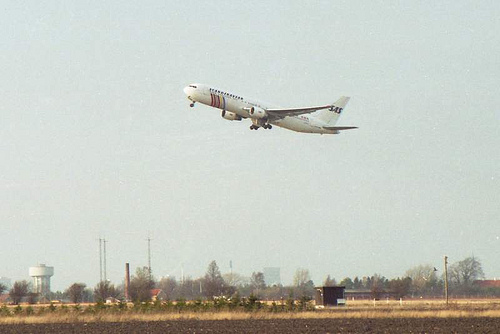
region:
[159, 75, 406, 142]
a plane taking off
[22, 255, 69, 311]
water tower in the distance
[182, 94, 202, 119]
front landing gear on the plane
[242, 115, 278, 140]
rear landing gear of the plane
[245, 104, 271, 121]
jet engine of the plane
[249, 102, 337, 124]
left wing of the plane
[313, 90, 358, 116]
tail fin of the plane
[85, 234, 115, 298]
posts in the distance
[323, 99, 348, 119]
logo of the airline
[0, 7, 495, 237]
a light blue sky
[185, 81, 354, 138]
airplane flying in sky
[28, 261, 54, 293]
white water tower by tree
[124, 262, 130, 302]
brown brick smoke stack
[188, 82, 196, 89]
cockpit window on airplane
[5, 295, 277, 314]
green bushes by field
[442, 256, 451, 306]
brown wooden light pole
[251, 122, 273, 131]
black rubber plane tires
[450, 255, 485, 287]
tree with no leaves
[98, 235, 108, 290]
two wooden electrical towers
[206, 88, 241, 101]
windows on side of plane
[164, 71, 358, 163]
commercial airplane in sky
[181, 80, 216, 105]
nose of commercial airplane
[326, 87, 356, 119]
tail of commercial airplane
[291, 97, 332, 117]
wing of commercial airplane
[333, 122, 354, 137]
wing of commercial airplane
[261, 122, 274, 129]
wheel of commercial airplane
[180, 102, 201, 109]
wheel of commercial airplane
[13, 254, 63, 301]
water tower on ground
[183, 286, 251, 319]
trees in the field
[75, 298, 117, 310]
trees on the field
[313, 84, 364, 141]
tail of jet airliner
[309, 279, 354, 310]
small brown building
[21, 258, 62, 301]
white water tower in distance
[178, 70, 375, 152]
jet airplane just after takeoff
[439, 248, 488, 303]
large tree with no leaves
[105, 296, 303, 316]
row of green shrubs and bushes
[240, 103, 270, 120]
one engine of jet airplane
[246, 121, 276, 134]
landing gear of jet airplane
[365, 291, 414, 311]
3 small white fence posts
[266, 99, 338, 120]
wing of jet aircraft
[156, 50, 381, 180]
A plane flying through the air.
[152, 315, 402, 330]
The ground is grown.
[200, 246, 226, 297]
A tree on the ground.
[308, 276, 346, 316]
A small brown building.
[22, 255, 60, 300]
A small tower on the ground.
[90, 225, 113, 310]
Two poles on the ground.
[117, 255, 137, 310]
Another pole by itself.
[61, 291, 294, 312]
Some bushes on the ground.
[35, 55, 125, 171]
The sky is overcast.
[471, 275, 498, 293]
Another building in the distance.